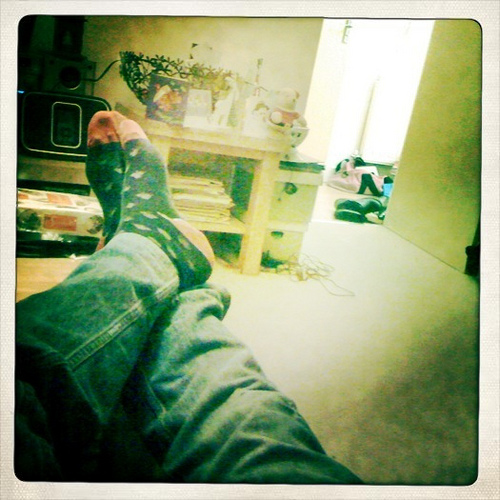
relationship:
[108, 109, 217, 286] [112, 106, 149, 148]
feet have tips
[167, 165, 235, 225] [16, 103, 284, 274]
sheets are on stand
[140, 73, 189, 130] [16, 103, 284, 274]
book on stand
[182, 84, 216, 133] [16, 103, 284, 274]
picture frame on stand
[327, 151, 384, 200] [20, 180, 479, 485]
bag on floor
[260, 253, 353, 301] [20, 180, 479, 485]
cords are on floor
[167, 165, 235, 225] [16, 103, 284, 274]
sheets are under stand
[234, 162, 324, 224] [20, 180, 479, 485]
boxes are on floor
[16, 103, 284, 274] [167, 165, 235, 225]
stand filled with sheets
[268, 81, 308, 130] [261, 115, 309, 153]
teddy bear in bowl